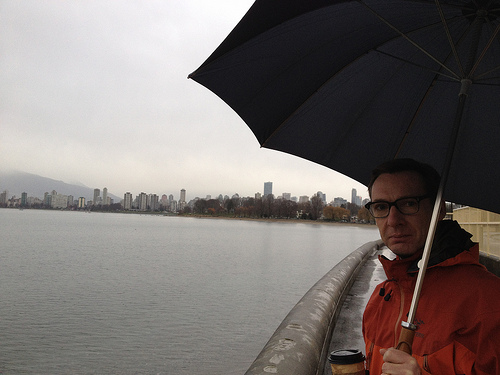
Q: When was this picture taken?
A: It was taken in the day time.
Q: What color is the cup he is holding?
A: The cup is brown.